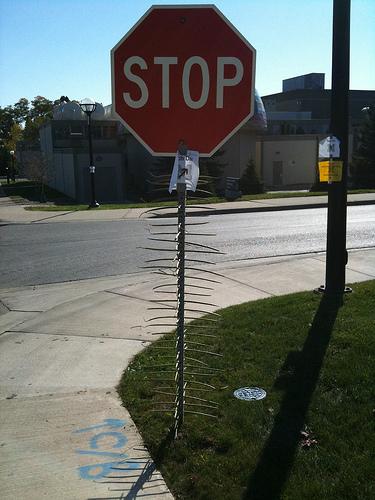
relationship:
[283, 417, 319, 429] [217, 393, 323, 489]
leaf on grass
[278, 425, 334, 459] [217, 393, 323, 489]
leave on grass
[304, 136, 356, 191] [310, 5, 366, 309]
paper on pole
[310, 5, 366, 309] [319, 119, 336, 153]
pole has spikes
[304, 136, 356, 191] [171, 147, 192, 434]
paper on pole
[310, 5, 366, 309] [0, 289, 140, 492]
pole near sidewalk